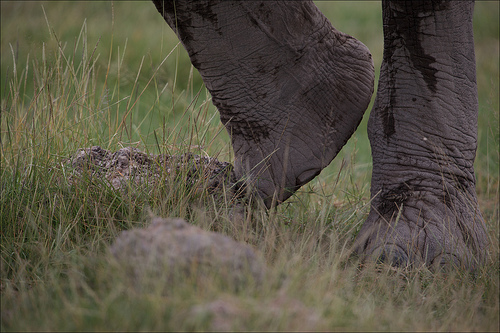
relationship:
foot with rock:
[197, 40, 397, 217] [69, 131, 294, 239]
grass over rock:
[23, 88, 213, 178] [77, 150, 264, 247]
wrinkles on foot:
[249, 51, 365, 128] [199, 40, 439, 230]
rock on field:
[103, 215, 270, 288] [3, 2, 483, 331]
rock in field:
[103, 206, 278, 286] [3, 2, 483, 331]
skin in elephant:
[390, 100, 462, 210] [151, 1, 484, 272]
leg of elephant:
[152, 0, 382, 224] [151, 1, 484, 272]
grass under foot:
[0, 0, 500, 333] [177, 20, 377, 230]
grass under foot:
[0, 0, 500, 333] [347, 112, 477, 278]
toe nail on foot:
[359, 239, 414, 269] [350, 195, 484, 294]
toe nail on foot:
[427, 249, 467, 280] [350, 195, 484, 294]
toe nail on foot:
[242, 181, 279, 210] [202, 29, 381, 213]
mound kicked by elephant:
[57, 140, 250, 227] [151, 1, 484, 272]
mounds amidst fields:
[92, 185, 275, 311] [16, 64, 387, 315]